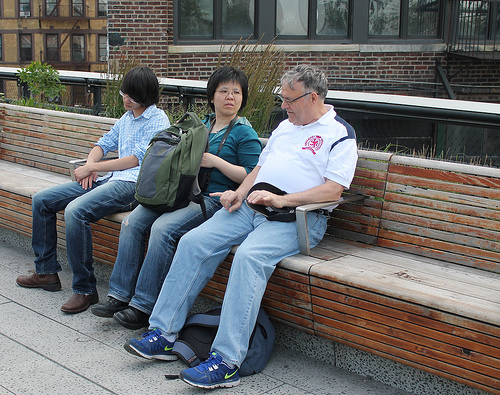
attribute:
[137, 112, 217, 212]
backpack — green, black on green, green with black, black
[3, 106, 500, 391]
bench — faded, wood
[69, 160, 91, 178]
armrest — metal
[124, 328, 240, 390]
shoes — blue, tennis shoes, blue with green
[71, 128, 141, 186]
arms — crossed, crossed]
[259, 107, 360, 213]
shirt — white, white with blue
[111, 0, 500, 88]
wall — brick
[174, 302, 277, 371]
bag — backpack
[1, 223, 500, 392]
sidewalk — concrete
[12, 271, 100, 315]
shoes — brown, pair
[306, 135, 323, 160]
logo — red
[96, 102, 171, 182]
shirt — plaid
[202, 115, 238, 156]
strap — black